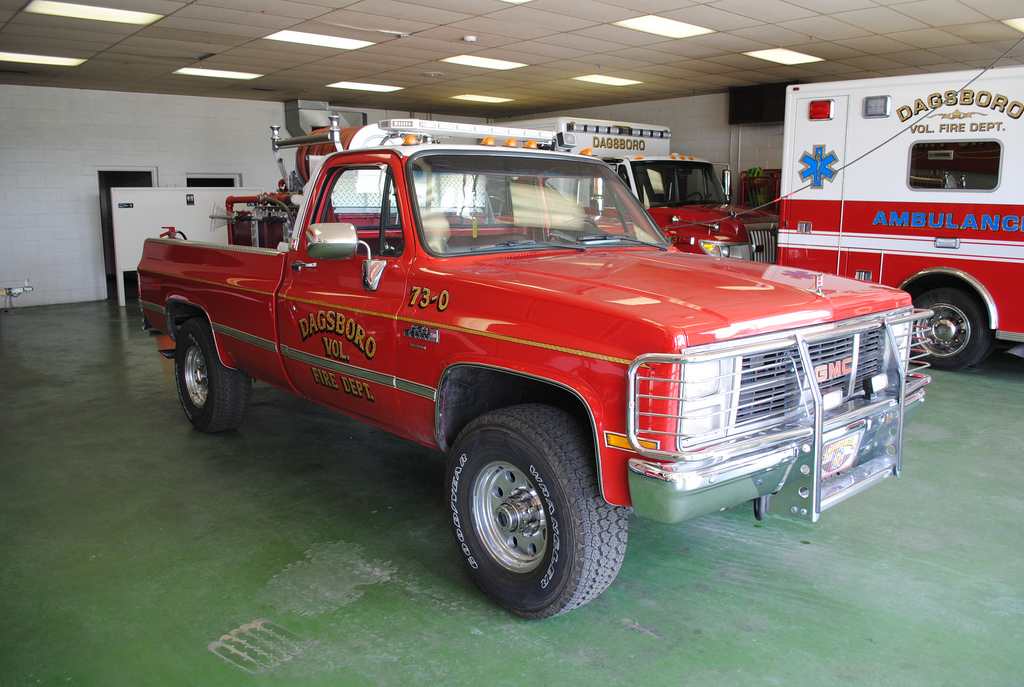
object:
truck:
[139, 135, 935, 620]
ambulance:
[777, 64, 1024, 368]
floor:
[5, 299, 1023, 681]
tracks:
[206, 617, 315, 674]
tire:
[444, 403, 628, 619]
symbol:
[799, 144, 840, 189]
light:
[438, 54, 531, 70]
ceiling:
[2, 2, 1024, 118]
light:
[807, 99, 834, 121]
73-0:
[408, 286, 451, 312]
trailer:
[380, 116, 673, 157]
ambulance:
[476, 117, 780, 264]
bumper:
[627, 305, 934, 524]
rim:
[473, 461, 549, 573]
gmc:
[814, 357, 852, 383]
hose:
[295, 123, 405, 186]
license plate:
[821, 431, 862, 479]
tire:
[175, 316, 252, 433]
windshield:
[413, 155, 675, 253]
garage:
[0, 1, 1022, 684]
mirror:
[306, 223, 389, 292]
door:
[276, 151, 416, 441]